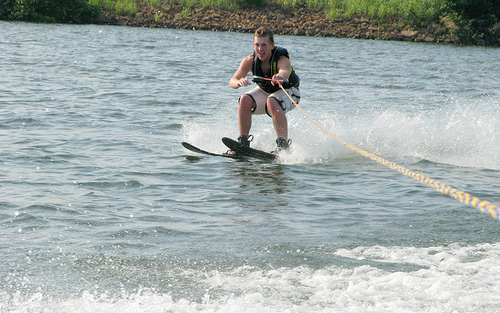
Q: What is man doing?
A: Kneeboarding.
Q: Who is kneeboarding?
A: A man.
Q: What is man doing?
A: Kneeboarding.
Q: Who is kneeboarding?
A: A man.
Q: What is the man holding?
A: Rope.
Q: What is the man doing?
A: Skiing on the water.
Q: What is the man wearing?
A: Life vest.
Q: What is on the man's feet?
A: Water skis.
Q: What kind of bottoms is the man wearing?
A: Swim trunks.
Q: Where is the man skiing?
A: Lake.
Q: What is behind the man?
A: Grass.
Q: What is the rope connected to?
A: A boat.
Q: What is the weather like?
A: Sunny.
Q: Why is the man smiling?
A: He's having fun.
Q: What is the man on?
A: Water skis.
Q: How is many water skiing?
A: With tow rope.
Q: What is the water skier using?
A: Tow rope.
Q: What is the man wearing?
A: A life jacket.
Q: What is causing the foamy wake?
A: The boat.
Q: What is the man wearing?
A: White swim trunks.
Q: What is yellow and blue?
A: Rope.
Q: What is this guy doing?
A: Water skiiing.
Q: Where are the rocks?
A: Riverbank.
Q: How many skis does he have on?
A: 2.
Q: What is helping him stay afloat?
A: Rope.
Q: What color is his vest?
A: Black.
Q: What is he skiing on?
A: Water.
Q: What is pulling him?
A: Boat.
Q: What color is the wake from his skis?
A: White.